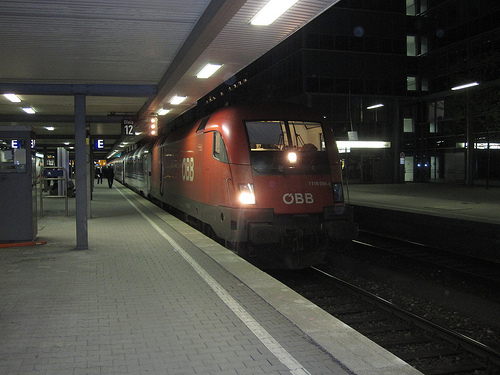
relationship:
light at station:
[19, 106, 37, 115] [0, 0, 499, 374]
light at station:
[194, 62, 223, 82] [4, 0, 498, 370]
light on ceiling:
[3, 93, 21, 106] [1, 0, 244, 148]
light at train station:
[246, 0, 296, 29] [22, 95, 482, 357]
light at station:
[148, 116, 161, 137] [23, 71, 497, 352]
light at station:
[246, 1, 309, 34] [0, 0, 499, 374]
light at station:
[194, 62, 223, 82] [0, 0, 499, 374]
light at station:
[153, 107, 174, 121] [0, 0, 499, 374]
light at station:
[3, 93, 21, 106] [0, 0, 499, 374]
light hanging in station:
[93, 132, 105, 150] [0, 0, 499, 374]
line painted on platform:
[111, 180, 313, 374] [1, 179, 420, 374]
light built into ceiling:
[194, 62, 223, 82] [2, 0, 349, 154]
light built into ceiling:
[174, 37, 256, 104] [2, 0, 349, 154]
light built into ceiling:
[222, 177, 284, 215] [2, 0, 349, 154]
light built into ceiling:
[3, 94, 22, 105] [2, 0, 349, 154]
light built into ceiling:
[19, 106, 37, 115] [2, 0, 349, 154]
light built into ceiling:
[246, 0, 296, 29] [2, 0, 349, 154]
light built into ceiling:
[169, 90, 189, 106] [2, 0, 349, 154]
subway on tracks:
[122, 104, 389, 259] [316, 254, 497, 368]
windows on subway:
[237, 94, 367, 218] [101, 95, 345, 252]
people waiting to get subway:
[63, 158, 117, 188] [0, 0, 425, 375]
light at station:
[246, 0, 296, 29] [0, 0, 499, 374]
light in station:
[8, 135, 20, 149] [0, 0, 499, 374]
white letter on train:
[280, 191, 296, 207] [99, 96, 356, 272]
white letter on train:
[291, 191, 306, 206] [99, 96, 356, 272]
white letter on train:
[300, 191, 314, 204] [99, 96, 356, 272]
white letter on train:
[187, 158, 197, 180] [99, 96, 356, 272]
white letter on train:
[177, 158, 188, 183] [99, 96, 356, 272]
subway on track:
[106, 95, 357, 273] [327, 188, 496, 352]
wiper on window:
[293, 131, 308, 146] [214, 116, 332, 185]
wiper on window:
[273, 127, 288, 148] [214, 116, 332, 185]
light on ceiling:
[19, 106, 37, 115] [2, 0, 349, 154]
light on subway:
[235, 189, 255, 206] [106, 106, 345, 258]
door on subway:
[158, 147, 172, 203] [102, 117, 350, 261]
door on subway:
[142, 153, 154, 193] [102, 117, 350, 261]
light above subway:
[194, 62, 223, 82] [65, 105, 405, 336]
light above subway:
[168, 93, 187, 108] [65, 105, 405, 336]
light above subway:
[246, 0, 296, 29] [65, 105, 405, 336]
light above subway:
[153, 106, 173, 120] [65, 105, 405, 336]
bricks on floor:
[52, 271, 194, 366] [0, 178, 422, 374]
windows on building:
[401, 45, 436, 95] [385, 0, 447, 187]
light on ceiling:
[46, 122, 55, 133] [4, 37, 178, 124]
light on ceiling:
[19, 106, 37, 115] [4, 37, 178, 124]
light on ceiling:
[3, 93, 21, 106] [4, 37, 178, 124]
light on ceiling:
[168, 93, 187, 108] [4, 37, 178, 124]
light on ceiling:
[194, 62, 223, 82] [4, 37, 178, 124]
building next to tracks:
[223, 0, 499, 189] [277, 229, 498, 369]